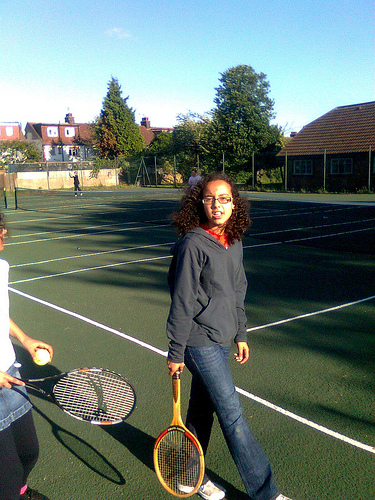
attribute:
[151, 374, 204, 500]
tennis racket — yellow, red, wood, wooden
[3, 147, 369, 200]
fence — chain link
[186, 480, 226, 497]
shoe — white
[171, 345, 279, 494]
jeans — blue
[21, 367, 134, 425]
tennis racket — aluminum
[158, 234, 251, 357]
sweatshirt — gray, dark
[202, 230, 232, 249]
undershirt — red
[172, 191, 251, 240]
hair — brown, curly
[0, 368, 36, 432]
skirt — denim, blue